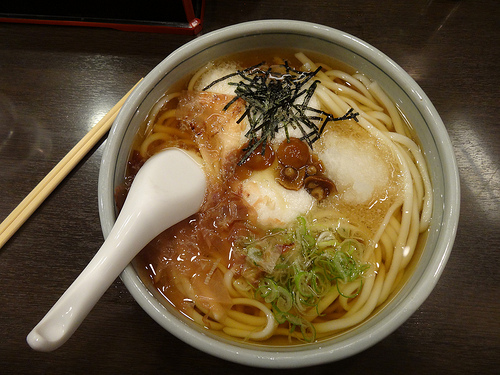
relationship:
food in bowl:
[127, 48, 435, 339] [96, 15, 464, 374]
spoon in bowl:
[28, 146, 207, 351] [96, 15, 464, 374]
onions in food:
[252, 214, 366, 336] [127, 48, 435, 339]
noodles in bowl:
[323, 75, 381, 115] [96, 15, 464, 374]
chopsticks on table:
[0, 73, 149, 244] [1, 1, 498, 374]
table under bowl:
[1, 1, 498, 374] [96, 15, 464, 374]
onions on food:
[252, 214, 366, 336] [127, 48, 435, 339]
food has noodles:
[127, 48, 435, 339] [223, 293, 275, 341]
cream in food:
[319, 129, 388, 207] [127, 48, 435, 339]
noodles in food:
[395, 132, 422, 260] [127, 48, 435, 339]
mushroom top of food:
[275, 138, 313, 167] [127, 48, 435, 339]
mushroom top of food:
[273, 161, 308, 190] [127, 48, 435, 339]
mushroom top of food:
[303, 171, 338, 200] [127, 48, 435, 339]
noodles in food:
[323, 75, 381, 115] [127, 48, 435, 339]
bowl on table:
[96, 15, 464, 374] [1, 1, 498, 374]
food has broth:
[127, 48, 435, 339] [138, 250, 164, 265]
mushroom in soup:
[275, 138, 313, 167] [127, 48, 435, 339]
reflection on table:
[1, 91, 57, 202] [1, 1, 498, 374]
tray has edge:
[1, 1, 203, 36] [0, 16, 198, 36]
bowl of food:
[96, 15, 464, 374] [127, 48, 435, 339]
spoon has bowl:
[28, 146, 207, 351] [97, 18, 463, 368]